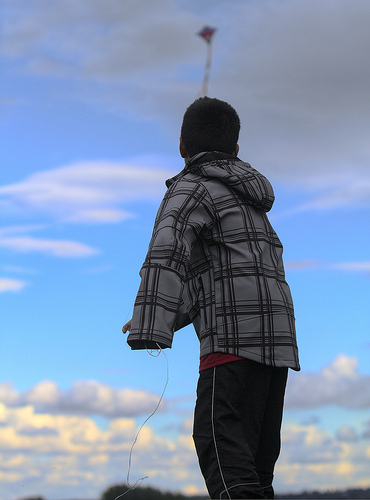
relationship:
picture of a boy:
[2, 4, 367, 496] [121, 95, 299, 495]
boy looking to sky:
[121, 95, 299, 495] [0, 1, 368, 481]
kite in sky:
[193, 21, 218, 97] [0, 1, 368, 481]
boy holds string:
[121, 95, 299, 495] [127, 342, 170, 500]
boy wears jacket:
[121, 95, 299, 495] [126, 151, 302, 372]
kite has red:
[193, 21, 218, 97] [202, 30, 218, 36]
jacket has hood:
[126, 151, 302, 372] [185, 148, 277, 210]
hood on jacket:
[185, 148, 277, 210] [126, 151, 302, 372]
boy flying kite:
[121, 95, 299, 495] [193, 21, 218, 97]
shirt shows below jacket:
[192, 353, 249, 371] [126, 151, 302, 372]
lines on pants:
[206, 368, 228, 500] [192, 358, 289, 499]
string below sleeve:
[127, 342, 170, 500] [125, 176, 219, 356]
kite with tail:
[193, 21, 218, 97] [194, 43, 220, 92]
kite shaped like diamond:
[193, 21, 218, 97] [197, 20, 220, 46]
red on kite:
[202, 30, 218, 36] [193, 21, 218, 97]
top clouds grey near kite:
[2, 4, 367, 170] [193, 21, 218, 97]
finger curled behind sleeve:
[119, 315, 135, 340] [125, 176, 219, 356]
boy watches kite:
[121, 95, 299, 495] [193, 21, 218, 97]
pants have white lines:
[192, 358, 289, 499] [206, 368, 228, 500]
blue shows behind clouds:
[1, 300, 119, 375] [2, 160, 192, 491]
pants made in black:
[192, 358, 289, 499] [228, 378, 275, 473]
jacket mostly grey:
[126, 151, 302, 372] [231, 276, 257, 305]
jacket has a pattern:
[126, 151, 302, 372] [201, 192, 271, 345]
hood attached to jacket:
[185, 148, 277, 210] [126, 151, 302, 372]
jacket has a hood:
[126, 151, 302, 372] [185, 148, 277, 210]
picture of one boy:
[2, 4, 367, 496] [121, 95, 299, 495]